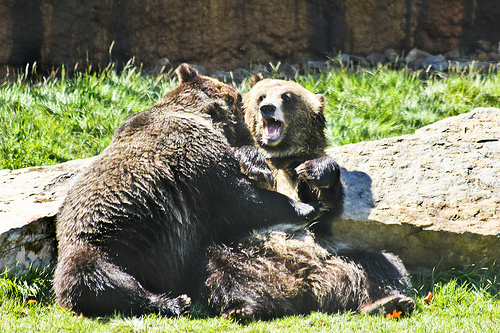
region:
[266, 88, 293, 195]
This bear looks very angry here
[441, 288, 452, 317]
There is a patch of green grass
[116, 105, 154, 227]
This bear looks like it's being assertive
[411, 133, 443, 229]
There is a large slab of rock here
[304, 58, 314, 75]
There are assorted rocks in the distance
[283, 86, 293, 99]
This bear has strong black eyes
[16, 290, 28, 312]
There is a leaf that is visible here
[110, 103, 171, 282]
Jackson Mingus took the photo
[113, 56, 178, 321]
There is a great deal of detail here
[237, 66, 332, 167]
head of a bear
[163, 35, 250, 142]
head of a bear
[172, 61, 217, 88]
ear of a bear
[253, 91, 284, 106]
eye of a bear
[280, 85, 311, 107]
eye of a bear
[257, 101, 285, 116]
nose of a bear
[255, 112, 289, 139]
mouth of a bear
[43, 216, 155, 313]
leg of a bear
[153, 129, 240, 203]
arm of a bear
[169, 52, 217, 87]
an ear of a bear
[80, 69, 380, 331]
two bears near rocks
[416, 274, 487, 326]
green grass around bears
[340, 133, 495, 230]
large and brown rocks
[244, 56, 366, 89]
bear has brown ears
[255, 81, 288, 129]
bear has black nose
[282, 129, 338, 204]
bear has brown paws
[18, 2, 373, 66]
brown wall behind grass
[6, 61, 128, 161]
thick green grass behind rocks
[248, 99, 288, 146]
bear has open mouth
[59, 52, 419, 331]
Two bears on the ground fighting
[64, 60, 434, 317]
Two bears on the ground fighting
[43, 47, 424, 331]
Two bears on the ground fighting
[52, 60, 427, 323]
Two bears on the ground fighting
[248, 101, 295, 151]
bear with its mouth open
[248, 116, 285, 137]
bear with its mouth open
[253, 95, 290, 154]
bear with its mouth open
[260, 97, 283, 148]
bear with its mouth open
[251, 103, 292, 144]
bear with its mouth open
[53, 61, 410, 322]
Two bears play fighting and cuddling.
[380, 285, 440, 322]
Two flowers in front of the bears.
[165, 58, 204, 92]
A small cute bear ear.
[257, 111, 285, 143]
The mouth of a bear that is play fighting.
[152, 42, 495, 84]
Some rocks behind two bears.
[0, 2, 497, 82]
A brown wall behind two bears.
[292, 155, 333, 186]
The left paw of a bear that is playing.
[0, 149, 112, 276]
The left side of a large rock.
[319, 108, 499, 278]
The right side of a large rock.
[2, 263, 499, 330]
some grass in front of bears.